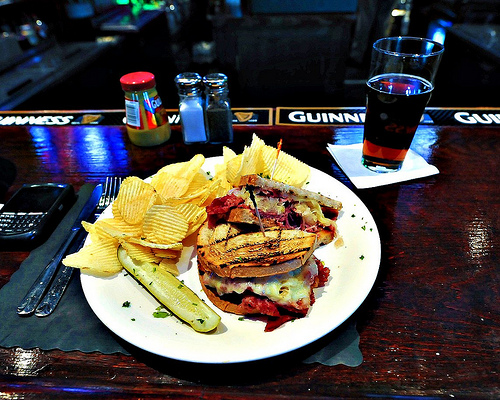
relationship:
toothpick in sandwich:
[242, 185, 267, 237] [194, 172, 341, 315]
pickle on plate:
[114, 243, 220, 335] [81, 151, 383, 367]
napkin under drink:
[326, 142, 440, 190] [359, 33, 446, 175]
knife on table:
[18, 184, 102, 318] [1, 2, 498, 397]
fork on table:
[31, 171, 126, 316] [1, 2, 498, 397]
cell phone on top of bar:
[1, 176, 76, 243] [8, 120, 498, 397]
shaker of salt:
[173, 70, 202, 148] [178, 93, 206, 144]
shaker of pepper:
[200, 67, 231, 143] [207, 93, 232, 150]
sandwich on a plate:
[196, 176, 345, 327] [81, 151, 383, 367]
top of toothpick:
[275, 137, 285, 156] [260, 127, 299, 188]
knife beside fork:
[18, 184, 102, 318] [31, 171, 126, 316]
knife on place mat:
[18, 184, 102, 318] [5, 189, 107, 350]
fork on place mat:
[31, 171, 126, 316] [5, 189, 107, 350]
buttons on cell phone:
[22, 213, 39, 221] [0, 178, 67, 242]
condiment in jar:
[116, 65, 170, 144] [114, 66, 174, 146]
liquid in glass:
[357, 66, 430, 162] [361, 35, 446, 172]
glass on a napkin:
[361, 35, 446, 172] [332, 142, 443, 189]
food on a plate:
[118, 245, 221, 332] [81, 151, 383, 367]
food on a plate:
[196, 216, 330, 331] [81, 151, 383, 367]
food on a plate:
[206, 173, 343, 244] [81, 151, 383, 367]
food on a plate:
[153, 207, 188, 243] [81, 151, 383, 367]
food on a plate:
[261, 145, 309, 184] [81, 151, 383, 367]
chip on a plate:
[116, 176, 156, 223] [50, 131, 400, 397]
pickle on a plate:
[114, 243, 220, 335] [81, 151, 383, 367]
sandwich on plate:
[194, 173, 344, 332] [81, 151, 383, 367]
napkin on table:
[335, 121, 440, 208] [2, 104, 494, 395]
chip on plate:
[116, 172, 153, 223] [81, 151, 383, 367]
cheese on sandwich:
[259, 277, 310, 304] [196, 176, 345, 327]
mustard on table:
[118, 67, 173, 149] [2, 104, 494, 395]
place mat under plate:
[50, 290, 117, 356] [158, 334, 295, 363]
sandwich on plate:
[194, 173, 344, 332] [72, 142, 387, 374]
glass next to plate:
[361, 35, 446, 172] [72, 142, 387, 374]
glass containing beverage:
[361, 35, 446, 172] [360, 72, 434, 170]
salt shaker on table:
[172, 65, 207, 144] [2, 104, 494, 395]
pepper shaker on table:
[199, 66, 234, 144] [2, 104, 494, 395]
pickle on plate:
[117, 243, 221, 333] [319, 245, 392, 337]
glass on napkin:
[361, 35, 446, 172] [322, 143, 441, 191]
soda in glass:
[366, 67, 435, 180] [361, 35, 446, 172]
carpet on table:
[410, 198, 487, 338] [2, 104, 494, 395]